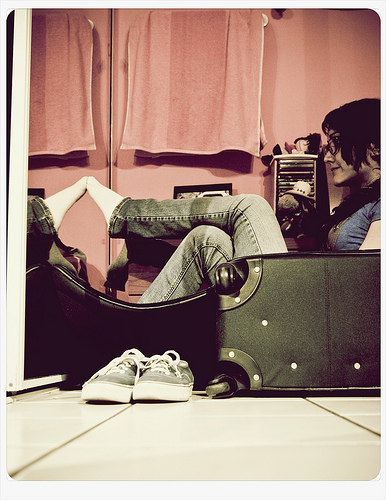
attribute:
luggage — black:
[208, 248, 385, 396]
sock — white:
[82, 174, 125, 228]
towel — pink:
[118, 14, 273, 158]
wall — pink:
[113, 11, 322, 193]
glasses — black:
[318, 138, 344, 156]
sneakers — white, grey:
[75, 345, 202, 407]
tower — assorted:
[274, 153, 324, 244]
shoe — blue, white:
[129, 348, 202, 406]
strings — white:
[143, 350, 182, 376]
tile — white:
[81, 400, 266, 452]